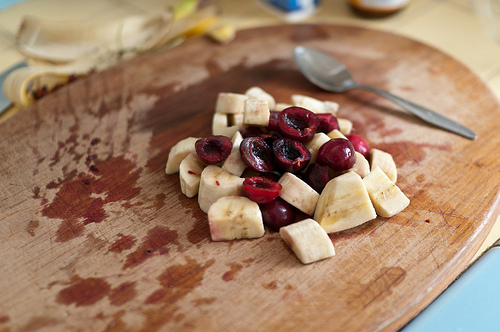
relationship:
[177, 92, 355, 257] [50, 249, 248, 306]
bananas & cherries on cutting board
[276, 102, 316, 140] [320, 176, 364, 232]
cherry next to banana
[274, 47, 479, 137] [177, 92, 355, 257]
spoon by bananas & cherries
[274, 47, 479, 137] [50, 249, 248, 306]
spoon on cutting board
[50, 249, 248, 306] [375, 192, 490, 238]
cutting board has scratches & scuffs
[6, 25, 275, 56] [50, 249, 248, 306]
banana peel behind cutting board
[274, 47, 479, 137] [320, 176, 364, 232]
spoon by banana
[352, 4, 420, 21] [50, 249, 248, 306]
jar behind cutting board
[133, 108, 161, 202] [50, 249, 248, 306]
cherry juice on cutting board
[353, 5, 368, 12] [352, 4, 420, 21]
edge of jar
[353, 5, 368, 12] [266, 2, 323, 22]
edge of container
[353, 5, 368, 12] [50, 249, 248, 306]
edge of cutting board